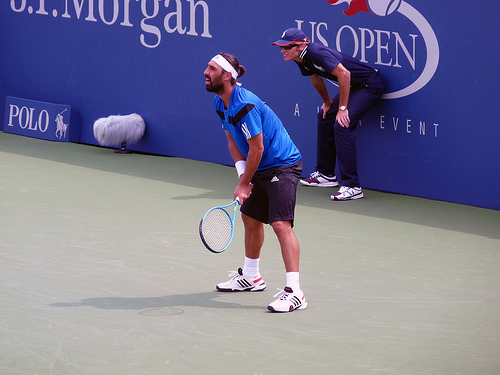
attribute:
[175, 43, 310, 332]
man — tennis player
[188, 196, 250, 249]
tennis racket — blue, black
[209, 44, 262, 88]
headband — white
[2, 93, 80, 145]
ad — blue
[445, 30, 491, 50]
wall — blue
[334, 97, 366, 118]
watch — gold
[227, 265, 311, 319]
white shoes — striped, black, man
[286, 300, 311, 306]
stripes — black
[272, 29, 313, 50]
hat — red, blue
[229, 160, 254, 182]
wristband — white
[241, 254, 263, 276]
sock — white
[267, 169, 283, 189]
emblem — adidas, white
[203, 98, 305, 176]
shirt — blue